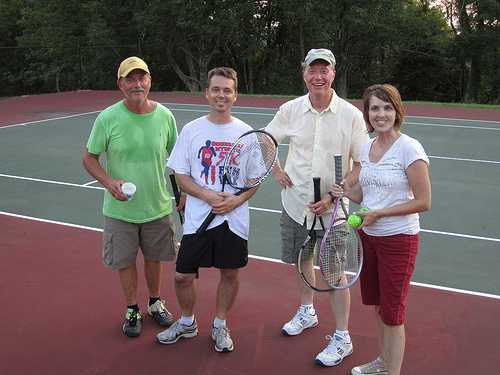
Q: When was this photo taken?
A: Daylight.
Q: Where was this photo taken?
A: Tennis court.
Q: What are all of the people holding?
A: Tennis rackets.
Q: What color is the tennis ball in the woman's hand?
A: Green.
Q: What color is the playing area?
A: Green.